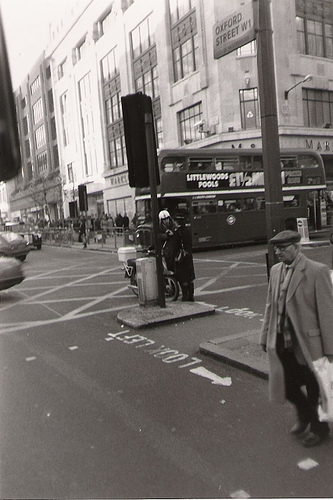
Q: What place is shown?
A: It is a road.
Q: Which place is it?
A: It is a road.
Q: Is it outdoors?
A: Yes, it is outdoors.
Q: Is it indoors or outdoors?
A: It is outdoors.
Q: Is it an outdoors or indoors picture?
A: It is outdoors.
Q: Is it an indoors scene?
A: No, it is outdoors.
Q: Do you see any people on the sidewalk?
A: Yes, there are people on the sidewalk.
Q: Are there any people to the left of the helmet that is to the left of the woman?
A: Yes, there are people to the left of the helmet.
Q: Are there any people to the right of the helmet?
A: No, the people are to the left of the helmet.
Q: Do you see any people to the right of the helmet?
A: No, the people are to the left of the helmet.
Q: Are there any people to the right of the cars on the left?
A: Yes, there are people to the right of the cars.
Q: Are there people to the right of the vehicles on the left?
A: Yes, there are people to the right of the cars.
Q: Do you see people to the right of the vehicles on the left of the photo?
A: Yes, there are people to the right of the cars.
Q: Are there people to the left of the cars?
A: No, the people are to the right of the cars.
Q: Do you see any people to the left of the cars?
A: No, the people are to the right of the cars.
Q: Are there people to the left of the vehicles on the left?
A: No, the people are to the right of the cars.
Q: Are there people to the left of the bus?
A: Yes, there are people to the left of the bus.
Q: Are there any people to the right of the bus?
A: No, the people are to the left of the bus.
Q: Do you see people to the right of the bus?
A: No, the people are to the left of the bus.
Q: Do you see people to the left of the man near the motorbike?
A: Yes, there are people to the left of the man.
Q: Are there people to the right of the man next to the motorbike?
A: No, the people are to the left of the man.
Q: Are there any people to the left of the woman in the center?
A: Yes, there are people to the left of the woman.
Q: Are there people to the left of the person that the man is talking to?
A: Yes, there are people to the left of the woman.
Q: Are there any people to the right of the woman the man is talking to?
A: No, the people are to the left of the woman.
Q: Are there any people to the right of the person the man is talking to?
A: No, the people are to the left of the woman.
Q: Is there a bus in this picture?
A: Yes, there is a bus.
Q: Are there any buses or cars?
A: Yes, there is a bus.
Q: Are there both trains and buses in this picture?
A: No, there is a bus but no trains.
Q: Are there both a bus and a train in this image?
A: No, there is a bus but no trains.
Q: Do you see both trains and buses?
A: No, there is a bus but no trains.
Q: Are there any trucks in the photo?
A: No, there are no trucks.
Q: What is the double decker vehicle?
A: The vehicle is a bus.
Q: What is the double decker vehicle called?
A: The vehicle is a bus.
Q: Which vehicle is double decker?
A: The vehicle is a bus.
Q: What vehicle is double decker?
A: The vehicle is a bus.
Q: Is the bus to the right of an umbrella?
A: No, the bus is to the right of a person.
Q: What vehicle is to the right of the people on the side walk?
A: The vehicle is a bus.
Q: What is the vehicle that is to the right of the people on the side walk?
A: The vehicle is a bus.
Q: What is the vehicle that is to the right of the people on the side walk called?
A: The vehicle is a bus.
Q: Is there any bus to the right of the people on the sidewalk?
A: Yes, there is a bus to the right of the people.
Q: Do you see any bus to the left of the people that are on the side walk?
A: No, the bus is to the right of the people.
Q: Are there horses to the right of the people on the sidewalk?
A: No, there is a bus to the right of the people.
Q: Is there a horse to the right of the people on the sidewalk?
A: No, there is a bus to the right of the people.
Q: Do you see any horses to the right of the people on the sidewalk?
A: No, there is a bus to the right of the people.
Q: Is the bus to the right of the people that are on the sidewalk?
A: Yes, the bus is to the right of the people.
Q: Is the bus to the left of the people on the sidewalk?
A: No, the bus is to the right of the people.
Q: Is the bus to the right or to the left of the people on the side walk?
A: The bus is to the right of the people.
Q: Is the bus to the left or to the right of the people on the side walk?
A: The bus is to the right of the people.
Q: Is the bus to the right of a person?
A: Yes, the bus is to the right of a person.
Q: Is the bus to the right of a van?
A: No, the bus is to the right of a person.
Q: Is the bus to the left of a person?
A: No, the bus is to the right of a person.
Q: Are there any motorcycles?
A: Yes, there is a motorcycle.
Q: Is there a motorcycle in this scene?
A: Yes, there is a motorcycle.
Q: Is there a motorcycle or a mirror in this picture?
A: Yes, there is a motorcycle.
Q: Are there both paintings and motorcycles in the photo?
A: No, there is a motorcycle but no paintings.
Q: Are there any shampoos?
A: No, there are no shampoos.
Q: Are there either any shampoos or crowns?
A: No, there are no shampoos or crowns.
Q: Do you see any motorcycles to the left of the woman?
A: Yes, there is a motorcycle to the left of the woman.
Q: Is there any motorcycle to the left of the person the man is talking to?
A: Yes, there is a motorcycle to the left of the woman.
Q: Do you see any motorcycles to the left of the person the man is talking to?
A: Yes, there is a motorcycle to the left of the woman.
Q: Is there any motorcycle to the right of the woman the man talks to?
A: No, the motorcycle is to the left of the woman.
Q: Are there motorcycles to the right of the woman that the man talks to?
A: No, the motorcycle is to the left of the woman.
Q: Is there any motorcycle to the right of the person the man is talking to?
A: No, the motorcycle is to the left of the woman.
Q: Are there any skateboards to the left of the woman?
A: No, there is a motorcycle to the left of the woman.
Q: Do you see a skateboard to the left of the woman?
A: No, there is a motorcycle to the left of the woman.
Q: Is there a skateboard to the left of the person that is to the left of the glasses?
A: No, there is a motorcycle to the left of the woman.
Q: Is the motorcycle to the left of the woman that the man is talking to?
A: Yes, the motorcycle is to the left of the woman.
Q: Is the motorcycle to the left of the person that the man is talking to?
A: Yes, the motorcycle is to the left of the woman.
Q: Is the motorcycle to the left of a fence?
A: No, the motorcycle is to the left of the woman.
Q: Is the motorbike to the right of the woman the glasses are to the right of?
A: No, the motorbike is to the left of the woman.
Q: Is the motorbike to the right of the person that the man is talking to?
A: No, the motorbike is to the left of the woman.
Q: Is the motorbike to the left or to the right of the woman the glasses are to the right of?
A: The motorbike is to the left of the woman.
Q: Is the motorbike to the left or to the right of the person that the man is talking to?
A: The motorbike is to the left of the woman.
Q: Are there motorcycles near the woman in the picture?
A: Yes, there is a motorcycle near the woman.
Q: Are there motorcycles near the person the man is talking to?
A: Yes, there is a motorcycle near the woman.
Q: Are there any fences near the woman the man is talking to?
A: No, there is a motorcycle near the woman.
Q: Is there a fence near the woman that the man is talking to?
A: No, there is a motorcycle near the woman.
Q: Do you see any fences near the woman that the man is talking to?
A: No, there is a motorcycle near the woman.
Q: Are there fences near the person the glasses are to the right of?
A: No, there is a motorcycle near the woman.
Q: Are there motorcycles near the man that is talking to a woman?
A: Yes, there is a motorcycle near the man.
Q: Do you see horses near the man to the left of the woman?
A: No, there is a motorcycle near the man.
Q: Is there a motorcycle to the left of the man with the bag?
A: Yes, there is a motorcycle to the left of the man.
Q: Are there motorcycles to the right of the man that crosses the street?
A: No, the motorcycle is to the left of the man.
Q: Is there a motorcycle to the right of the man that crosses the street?
A: No, the motorcycle is to the left of the man.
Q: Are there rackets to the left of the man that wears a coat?
A: No, there is a motorcycle to the left of the man.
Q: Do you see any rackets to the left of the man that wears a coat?
A: No, there is a motorcycle to the left of the man.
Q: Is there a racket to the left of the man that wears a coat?
A: No, there is a motorcycle to the left of the man.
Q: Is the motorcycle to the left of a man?
A: Yes, the motorcycle is to the left of a man.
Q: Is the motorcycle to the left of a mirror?
A: No, the motorcycle is to the left of a man.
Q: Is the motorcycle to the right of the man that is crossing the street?
A: No, the motorcycle is to the left of the man.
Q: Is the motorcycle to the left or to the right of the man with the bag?
A: The motorcycle is to the left of the man.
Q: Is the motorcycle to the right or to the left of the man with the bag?
A: The motorcycle is to the left of the man.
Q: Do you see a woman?
A: Yes, there is a woman.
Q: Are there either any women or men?
A: Yes, there is a woman.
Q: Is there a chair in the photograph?
A: No, there are no chairs.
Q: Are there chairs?
A: No, there are no chairs.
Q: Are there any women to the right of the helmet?
A: Yes, there is a woman to the right of the helmet.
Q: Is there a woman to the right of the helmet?
A: Yes, there is a woman to the right of the helmet.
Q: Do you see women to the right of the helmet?
A: Yes, there is a woman to the right of the helmet.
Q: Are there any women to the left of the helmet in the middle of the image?
A: No, the woman is to the right of the helmet.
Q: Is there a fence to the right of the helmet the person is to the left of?
A: No, there is a woman to the right of the helmet.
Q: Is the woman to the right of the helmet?
A: Yes, the woman is to the right of the helmet.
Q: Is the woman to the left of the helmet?
A: No, the woman is to the right of the helmet.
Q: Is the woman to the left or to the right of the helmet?
A: The woman is to the right of the helmet.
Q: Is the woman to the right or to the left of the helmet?
A: The woman is to the right of the helmet.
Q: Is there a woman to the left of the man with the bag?
A: Yes, there is a woman to the left of the man.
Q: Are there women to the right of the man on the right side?
A: No, the woman is to the left of the man.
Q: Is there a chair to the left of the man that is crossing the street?
A: No, there is a woman to the left of the man.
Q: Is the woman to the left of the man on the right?
A: Yes, the woman is to the left of the man.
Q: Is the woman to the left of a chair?
A: No, the woman is to the left of the man.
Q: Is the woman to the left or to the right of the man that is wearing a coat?
A: The woman is to the left of the man.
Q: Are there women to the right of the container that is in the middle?
A: Yes, there is a woman to the right of the container.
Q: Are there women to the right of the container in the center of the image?
A: Yes, there is a woman to the right of the container.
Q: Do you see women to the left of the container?
A: No, the woman is to the right of the container.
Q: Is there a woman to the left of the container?
A: No, the woman is to the right of the container.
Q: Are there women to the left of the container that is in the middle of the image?
A: No, the woman is to the right of the container.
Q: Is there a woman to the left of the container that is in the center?
A: No, the woman is to the right of the container.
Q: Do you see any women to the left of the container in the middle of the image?
A: No, the woman is to the right of the container.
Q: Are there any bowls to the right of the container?
A: No, there is a woman to the right of the container.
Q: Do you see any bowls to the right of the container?
A: No, there is a woman to the right of the container.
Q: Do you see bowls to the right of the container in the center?
A: No, there is a woman to the right of the container.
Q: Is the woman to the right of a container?
A: Yes, the woman is to the right of a container.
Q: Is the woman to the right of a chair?
A: No, the woman is to the right of a container.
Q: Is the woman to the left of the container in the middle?
A: No, the woman is to the right of the container.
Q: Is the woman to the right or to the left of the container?
A: The woman is to the right of the container.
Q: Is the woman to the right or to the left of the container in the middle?
A: The woman is to the right of the container.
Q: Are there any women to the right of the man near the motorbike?
A: Yes, there is a woman to the right of the man.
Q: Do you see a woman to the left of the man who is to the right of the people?
A: No, the woman is to the right of the man.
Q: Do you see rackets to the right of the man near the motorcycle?
A: No, there is a woman to the right of the man.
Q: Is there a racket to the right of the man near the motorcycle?
A: No, there is a woman to the right of the man.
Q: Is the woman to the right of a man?
A: Yes, the woman is to the right of a man.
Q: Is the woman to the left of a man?
A: No, the woman is to the right of a man.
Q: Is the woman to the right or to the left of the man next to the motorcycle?
A: The woman is to the right of the man.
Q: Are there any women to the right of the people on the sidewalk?
A: Yes, there is a woman to the right of the people.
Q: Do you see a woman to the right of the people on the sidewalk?
A: Yes, there is a woman to the right of the people.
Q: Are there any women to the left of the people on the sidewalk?
A: No, the woman is to the right of the people.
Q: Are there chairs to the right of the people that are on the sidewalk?
A: No, there is a woman to the right of the people.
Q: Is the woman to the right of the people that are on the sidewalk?
A: Yes, the woman is to the right of the people.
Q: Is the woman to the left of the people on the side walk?
A: No, the woman is to the right of the people.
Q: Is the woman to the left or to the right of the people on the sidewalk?
A: The woman is to the right of the people.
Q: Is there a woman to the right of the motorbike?
A: Yes, there is a woman to the right of the motorbike.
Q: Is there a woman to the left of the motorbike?
A: No, the woman is to the right of the motorbike.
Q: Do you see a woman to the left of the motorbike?
A: No, the woman is to the right of the motorbike.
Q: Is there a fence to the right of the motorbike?
A: No, there is a woman to the right of the motorbike.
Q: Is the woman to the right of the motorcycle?
A: Yes, the woman is to the right of the motorcycle.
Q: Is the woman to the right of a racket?
A: No, the woman is to the right of the motorcycle.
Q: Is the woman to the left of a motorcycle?
A: No, the woman is to the right of a motorcycle.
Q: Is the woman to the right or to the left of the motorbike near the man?
A: The woman is to the right of the motorbike.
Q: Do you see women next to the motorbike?
A: Yes, there is a woman next to the motorbike.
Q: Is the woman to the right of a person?
A: Yes, the woman is to the right of a person.